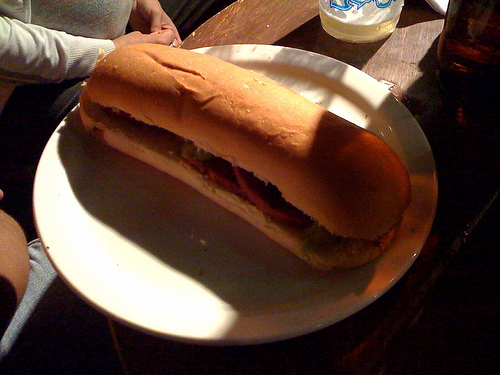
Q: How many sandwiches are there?
A: One.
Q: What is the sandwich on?
A: Plate.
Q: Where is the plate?
A: Table.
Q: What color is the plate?
A: White.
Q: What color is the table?
A: Brown.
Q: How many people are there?
A: Two.